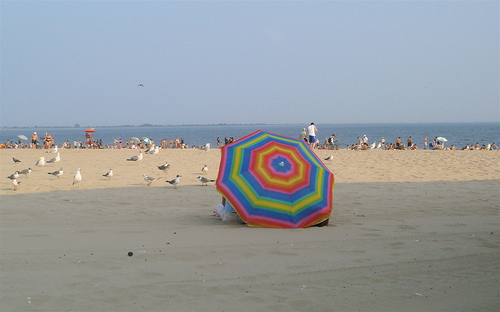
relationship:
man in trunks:
[29, 129, 39, 149] [28, 139, 38, 144]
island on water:
[95, 117, 202, 141] [79, 113, 489, 137]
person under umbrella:
[222, 195, 239, 226] [216, 130, 337, 226]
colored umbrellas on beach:
[215, 129, 335, 230] [2, 129, 499, 202]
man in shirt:
[303, 119, 317, 153] [304, 118, 317, 137]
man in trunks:
[303, 119, 317, 153] [303, 132, 316, 147]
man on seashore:
[303, 119, 317, 153] [1, 134, 493, 150]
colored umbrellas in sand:
[215, 129, 335, 230] [0, 144, 498, 309]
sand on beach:
[0, 144, 498, 309] [1, 145, 498, 307]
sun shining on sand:
[0, 149, 500, 200] [4, 147, 499, 181]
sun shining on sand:
[70, 149, 114, 165] [4, 147, 499, 181]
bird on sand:
[100, 167, 115, 181] [0, 144, 498, 309]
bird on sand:
[70, 165, 85, 185] [0, 144, 498, 309]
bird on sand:
[45, 164, 65, 179] [0, 144, 498, 309]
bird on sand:
[126, 147, 145, 167] [0, 144, 498, 309]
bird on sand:
[163, 169, 183, 190] [0, 144, 498, 309]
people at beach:
[2, 121, 499, 156] [1, 145, 498, 307]